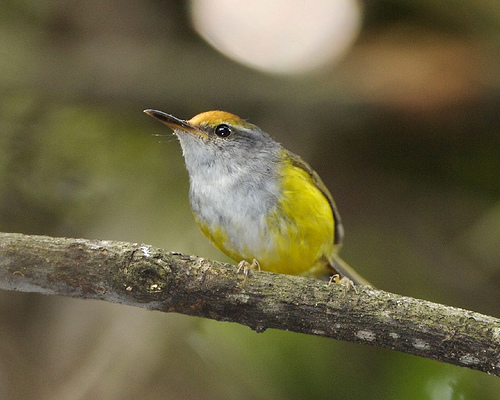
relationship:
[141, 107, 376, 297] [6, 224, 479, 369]
bird on tree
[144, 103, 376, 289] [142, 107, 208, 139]
bird has beak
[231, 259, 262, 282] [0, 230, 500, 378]
claw on branch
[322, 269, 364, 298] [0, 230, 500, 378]
claw on branch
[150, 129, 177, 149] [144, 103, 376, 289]
little whiskers on bird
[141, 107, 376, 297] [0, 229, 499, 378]
bird sitting on branch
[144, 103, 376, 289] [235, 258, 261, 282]
bird has claw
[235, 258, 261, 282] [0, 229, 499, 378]
claw on branch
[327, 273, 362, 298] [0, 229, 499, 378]
claw on branch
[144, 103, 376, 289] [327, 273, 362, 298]
bird has claw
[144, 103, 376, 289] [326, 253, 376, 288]
bird has birds tail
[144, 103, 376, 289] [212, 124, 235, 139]
bird has eye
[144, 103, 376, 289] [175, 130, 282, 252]
bird has white patch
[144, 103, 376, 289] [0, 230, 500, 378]
bird sitting on branch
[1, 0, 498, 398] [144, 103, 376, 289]
background behind bird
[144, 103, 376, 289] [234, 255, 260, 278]
bird has foot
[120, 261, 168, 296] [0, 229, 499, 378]
small knot on branch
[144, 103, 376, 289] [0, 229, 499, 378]
bird perched on branch